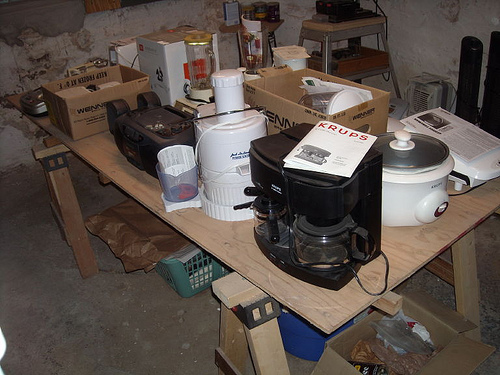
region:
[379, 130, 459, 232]
a crock pot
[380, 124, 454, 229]
a white crock pot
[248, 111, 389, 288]
a black coffee pot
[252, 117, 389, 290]
a black coffee pot with directions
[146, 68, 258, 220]
a white juicer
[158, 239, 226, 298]
a green laundry basket on the ground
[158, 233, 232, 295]
a green laundry basket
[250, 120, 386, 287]
a black coffee maker on a table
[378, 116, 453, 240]
a white crock pot on a table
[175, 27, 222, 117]
a blender on a table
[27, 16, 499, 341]
many small appliances on piece of makeshift table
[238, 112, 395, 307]
coffee maker with manual on top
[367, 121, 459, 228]
white rice maker with lid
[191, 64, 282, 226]
white juicer with cord wrapped around it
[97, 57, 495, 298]
assorted used small appliances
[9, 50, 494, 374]
piece of plywood on top of wooden sawhorses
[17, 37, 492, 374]
table made of plywood and sawhorses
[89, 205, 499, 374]
clutter under makeshift table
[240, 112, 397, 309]
black cappucino maker with manual resting on top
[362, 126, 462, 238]
white crock pot with grey lid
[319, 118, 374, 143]
The word KRUPS printed by color red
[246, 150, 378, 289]
A black coffee maker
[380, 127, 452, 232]
A white rice cooker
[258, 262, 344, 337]
some scratches on the table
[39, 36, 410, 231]
there are two brown boxes on the table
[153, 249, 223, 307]
A green basket under the table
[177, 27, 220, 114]
The blender has a color gold cover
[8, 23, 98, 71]
some dirt on the wall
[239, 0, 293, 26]
three canned paints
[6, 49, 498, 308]
a wooden table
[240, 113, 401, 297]
paper laying on top of the coffee maker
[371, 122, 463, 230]
white appliance with a lid on it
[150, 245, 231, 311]
green laundry basket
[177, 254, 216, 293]
holes in the basket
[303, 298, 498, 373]
cardboard box on the floor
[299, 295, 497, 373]
cardboard box is open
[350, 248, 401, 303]
black cord from the coffee maker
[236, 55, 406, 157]
cardboard box on the table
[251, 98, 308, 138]
black writing on the side of the box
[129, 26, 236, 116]
white and black box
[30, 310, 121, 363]
The ground is gray in color.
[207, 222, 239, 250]
The table is brown.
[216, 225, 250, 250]
The table is made from wood.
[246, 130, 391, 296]
The coffee machine is black.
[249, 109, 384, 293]
The coffee machine is on the table.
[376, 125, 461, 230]
The crockpot is white.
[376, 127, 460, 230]
The crockpot is on the table.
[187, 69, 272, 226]
The juicer is white.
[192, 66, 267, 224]
The juicer is on the table.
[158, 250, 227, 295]
The laundry basket is green.